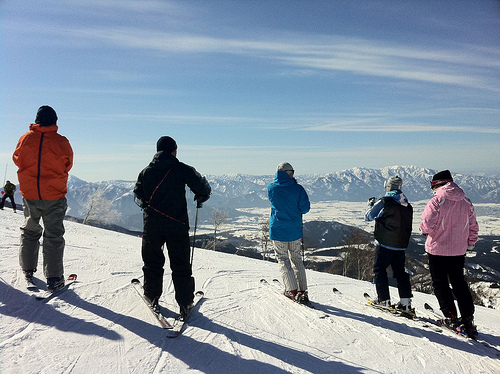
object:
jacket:
[10, 123, 73, 198]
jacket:
[132, 150, 211, 229]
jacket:
[262, 169, 311, 241]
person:
[418, 169, 479, 340]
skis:
[23, 273, 78, 311]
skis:
[132, 282, 205, 339]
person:
[258, 162, 311, 306]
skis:
[259, 270, 330, 319]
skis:
[365, 290, 438, 333]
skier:
[363, 175, 418, 322]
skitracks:
[201, 301, 241, 320]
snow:
[199, 309, 370, 368]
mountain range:
[56, 160, 494, 209]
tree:
[210, 211, 224, 249]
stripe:
[33, 133, 48, 198]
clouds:
[290, 26, 478, 92]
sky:
[187, 17, 438, 136]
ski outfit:
[130, 161, 212, 309]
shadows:
[163, 334, 213, 371]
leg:
[41, 199, 66, 289]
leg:
[17, 199, 43, 279]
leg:
[165, 217, 197, 307]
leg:
[139, 220, 167, 307]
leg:
[270, 233, 299, 294]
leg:
[285, 239, 310, 290]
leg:
[372, 246, 393, 303]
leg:
[390, 248, 412, 303]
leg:
[429, 254, 457, 337]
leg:
[448, 253, 473, 332]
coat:
[418, 182, 478, 257]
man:
[13, 105, 75, 299]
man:
[130, 133, 212, 338]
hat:
[153, 134, 179, 154]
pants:
[427, 252, 474, 332]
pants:
[18, 197, 63, 283]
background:
[6, 3, 493, 200]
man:
[1, 181, 18, 213]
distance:
[2, 152, 495, 233]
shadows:
[2, 280, 119, 372]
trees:
[74, 190, 122, 224]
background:
[4, 160, 494, 298]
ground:
[22, 324, 197, 367]